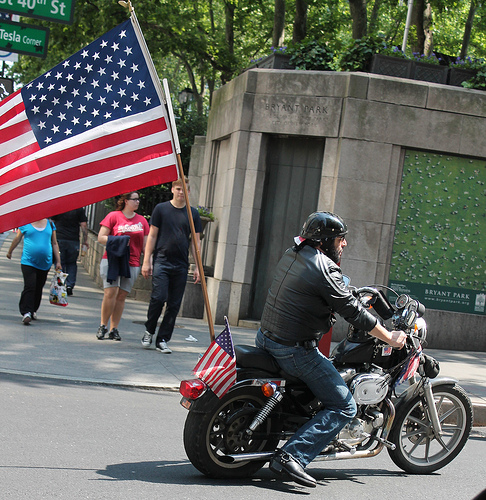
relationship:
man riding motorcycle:
[257, 208, 410, 488] [184, 287, 475, 481]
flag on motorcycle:
[1, 19, 177, 237] [184, 287, 475, 481]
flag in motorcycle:
[1, 19, 177, 237] [184, 287, 475, 481]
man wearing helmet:
[257, 208, 410, 488] [301, 206, 350, 249]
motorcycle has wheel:
[184, 287, 475, 481] [390, 380, 471, 471]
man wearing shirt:
[257, 208, 410, 488] [264, 244, 373, 347]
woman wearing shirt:
[93, 191, 162, 348] [99, 211, 156, 267]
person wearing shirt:
[0, 209, 69, 335] [19, 217, 58, 267]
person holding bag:
[0, 209, 69, 335] [50, 272, 78, 306]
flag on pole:
[1, 19, 177, 237] [177, 153, 217, 344]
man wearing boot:
[257, 208, 410, 488] [265, 446, 322, 487]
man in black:
[138, 173, 209, 355] [144, 203, 204, 331]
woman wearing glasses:
[93, 191, 162, 348] [127, 193, 144, 203]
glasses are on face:
[127, 193, 144, 203] [126, 193, 144, 215]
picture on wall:
[392, 143, 485, 317] [180, 66, 485, 343]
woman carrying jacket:
[93, 191, 162, 348] [108, 234, 127, 284]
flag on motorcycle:
[196, 323, 243, 401] [184, 287, 475, 481]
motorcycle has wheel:
[184, 287, 475, 481] [182, 380, 291, 485]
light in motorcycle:
[185, 379, 207, 401] [184, 287, 475, 481]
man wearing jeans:
[257, 208, 410, 488] [255, 331, 358, 455]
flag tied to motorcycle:
[1, 19, 177, 237] [184, 287, 475, 481]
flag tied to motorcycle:
[196, 323, 243, 401] [184, 287, 475, 481]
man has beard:
[257, 208, 410, 488] [332, 248, 344, 266]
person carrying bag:
[0, 209, 69, 335] [50, 272, 78, 306]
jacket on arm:
[108, 234, 127, 284] [97, 215, 126, 243]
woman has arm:
[93, 191, 162, 348] [97, 215, 126, 243]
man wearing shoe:
[138, 173, 209, 355] [140, 334, 152, 350]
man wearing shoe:
[138, 173, 209, 355] [155, 343, 176, 353]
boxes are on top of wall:
[348, 49, 452, 85] [180, 66, 485, 343]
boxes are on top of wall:
[240, 38, 332, 75] [180, 66, 485, 343]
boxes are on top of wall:
[451, 60, 485, 83] [180, 66, 485, 343]